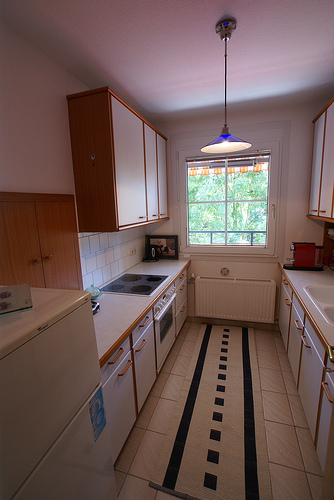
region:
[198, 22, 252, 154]
a ceiling light with blue shade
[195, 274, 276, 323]
a white radiator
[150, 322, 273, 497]
a black and tan patterned area rug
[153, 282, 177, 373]
a white built in oven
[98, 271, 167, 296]
a black stove top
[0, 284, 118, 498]
a white refrigerator freezer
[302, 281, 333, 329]
a white sink basin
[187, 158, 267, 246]
a white four paned window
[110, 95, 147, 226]
a white cabinet door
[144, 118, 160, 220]
a white cabinet door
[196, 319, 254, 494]
A black and white rug on the floor.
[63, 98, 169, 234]
Wooden cabinets in the kitchen.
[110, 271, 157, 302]
Four burners on the stove.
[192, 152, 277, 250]
A window in the kitchen.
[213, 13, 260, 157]
Light hanging from the ceiling.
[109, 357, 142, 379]
Brown handles on the cabinets.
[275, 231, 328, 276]
Appliance on the countertop.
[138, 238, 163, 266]
Teapot on the counter.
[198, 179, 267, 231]
Trees outside the window.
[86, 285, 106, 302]
A small glass on counter.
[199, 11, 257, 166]
A low down light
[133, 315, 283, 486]
A long black/white rug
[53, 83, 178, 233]
A row of three white cabinets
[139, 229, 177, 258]
A black picture frame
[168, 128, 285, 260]
A single white window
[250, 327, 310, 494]
A brown rough row of floor tiles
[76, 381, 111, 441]
A blue sticker/note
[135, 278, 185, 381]
A white oven/burners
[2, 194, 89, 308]
A brown wooden cabinet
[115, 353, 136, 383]
A brown wooden handle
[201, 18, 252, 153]
the hanging kitchen light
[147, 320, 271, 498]
the area rug in the kitchen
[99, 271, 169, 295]
the stovetop in the kitchen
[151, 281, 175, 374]
the oven in the kitchen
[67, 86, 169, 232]
the cabinets above the stove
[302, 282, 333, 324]
the white double sink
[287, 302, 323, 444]
the cabinet doors under the sink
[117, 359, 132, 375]
the handle on the cabinet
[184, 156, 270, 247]
the window in the kitchen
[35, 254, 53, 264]
the two wooden door knobs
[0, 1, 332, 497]
This is a kitchen scene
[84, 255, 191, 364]
A kitchen counter top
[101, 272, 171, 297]
A stove top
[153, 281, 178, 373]
This is an oven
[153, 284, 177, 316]
The oven's control knobs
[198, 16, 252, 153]
A light is hanging from the ceiling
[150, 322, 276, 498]
A rug is on the floor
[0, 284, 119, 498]
This is a refrigerator freezer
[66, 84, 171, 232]
Kitchen cabinets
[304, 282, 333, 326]
A kitchen sink